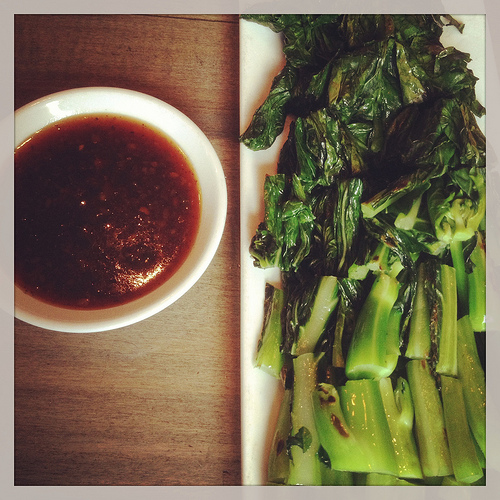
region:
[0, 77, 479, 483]
food on the table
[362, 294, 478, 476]
the food is sliced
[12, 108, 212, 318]
sauce in the bowl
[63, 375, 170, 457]
the table is wood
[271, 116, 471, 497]
vegetables in the plate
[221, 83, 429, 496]
the tray is rectangle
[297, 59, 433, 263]
the food is green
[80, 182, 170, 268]
the sauce is red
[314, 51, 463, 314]
these are the veges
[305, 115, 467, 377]
the veges are fried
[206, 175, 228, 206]
the plate is round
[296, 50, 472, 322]
the veges are fried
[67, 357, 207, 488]
this is the table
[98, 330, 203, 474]
the table is wooden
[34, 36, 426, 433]
this is a dinner food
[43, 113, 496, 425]
these are appetizers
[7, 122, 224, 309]
this is a condiment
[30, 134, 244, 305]
this condiment is red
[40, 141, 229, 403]
the condiment is in a bowl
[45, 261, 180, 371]
this is a small bowl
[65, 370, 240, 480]
this is a table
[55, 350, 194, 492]
the table is light brown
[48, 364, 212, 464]
the table top is wood grain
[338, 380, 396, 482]
vegetable on the plate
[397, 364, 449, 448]
vegetable on the plate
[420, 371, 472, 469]
vegetable on the plate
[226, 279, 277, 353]
vegetable on the plate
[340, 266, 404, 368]
vegetable on the plate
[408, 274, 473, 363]
vegetable on the plate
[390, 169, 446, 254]
vegetable on the plate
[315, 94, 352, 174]
vegetable on the plate